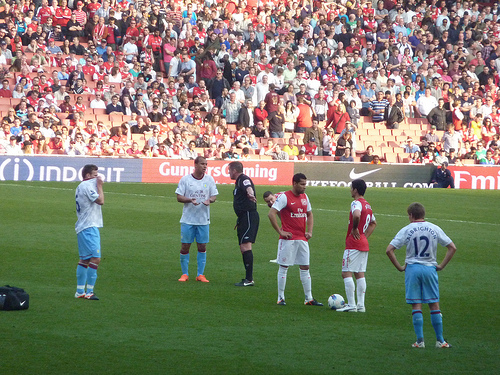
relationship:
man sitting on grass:
[425, 154, 454, 193] [4, 179, 498, 373]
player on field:
[333, 177, 379, 312] [2, 184, 494, 371]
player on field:
[264, 191, 285, 209] [2, 184, 494, 371]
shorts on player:
[168, 220, 219, 244] [385, 199, 462, 345]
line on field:
[376, 206, 406, 220] [2, 184, 494, 371]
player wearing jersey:
[267, 171, 322, 306] [271, 190, 311, 238]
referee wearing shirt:
[226, 160, 263, 290] [220, 172, 264, 215]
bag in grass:
[6, 280, 38, 315] [4, 179, 498, 373]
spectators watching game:
[0, 2, 485, 163] [4, 157, 499, 372]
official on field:
[232, 168, 252, 265] [3, 102, 497, 373]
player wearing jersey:
[59, 161, 107, 298] [227, 175, 266, 247]